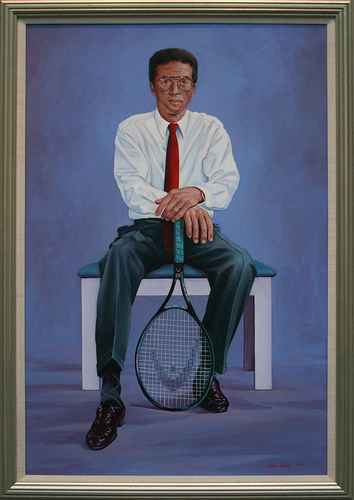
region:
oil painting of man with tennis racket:
[7, 9, 334, 479]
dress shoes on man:
[83, 367, 235, 453]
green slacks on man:
[100, 200, 254, 397]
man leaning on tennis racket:
[79, 36, 249, 450]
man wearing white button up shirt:
[80, 45, 245, 452]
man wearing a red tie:
[78, 44, 260, 452]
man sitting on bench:
[56, 48, 277, 446]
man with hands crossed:
[75, 31, 255, 452]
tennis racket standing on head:
[129, 202, 215, 417]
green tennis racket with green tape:
[130, 199, 217, 415]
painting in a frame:
[8, 10, 342, 480]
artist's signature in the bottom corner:
[265, 459, 308, 470]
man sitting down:
[75, 42, 275, 453]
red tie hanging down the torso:
[161, 127, 182, 213]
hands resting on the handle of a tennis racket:
[156, 185, 214, 252]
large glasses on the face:
[153, 72, 194, 93]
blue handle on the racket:
[168, 223, 189, 262]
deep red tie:
[162, 125, 185, 251]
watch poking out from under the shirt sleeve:
[197, 189, 210, 204]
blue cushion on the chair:
[76, 244, 278, 277]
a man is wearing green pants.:
[99, 294, 124, 338]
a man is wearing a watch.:
[192, 184, 204, 199]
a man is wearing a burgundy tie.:
[160, 119, 180, 189]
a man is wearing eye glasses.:
[150, 70, 193, 90]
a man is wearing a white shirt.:
[129, 138, 156, 175]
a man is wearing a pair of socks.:
[100, 369, 122, 395]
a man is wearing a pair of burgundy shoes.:
[84, 396, 125, 451]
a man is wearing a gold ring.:
[173, 200, 185, 212]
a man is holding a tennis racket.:
[129, 217, 218, 411]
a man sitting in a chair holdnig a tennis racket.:
[74, 46, 275, 452]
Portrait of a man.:
[0, 0, 351, 499]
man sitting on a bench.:
[84, 47, 252, 451]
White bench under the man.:
[72, 252, 284, 399]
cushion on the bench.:
[72, 258, 275, 278]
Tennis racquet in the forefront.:
[129, 207, 220, 415]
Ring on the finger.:
[170, 201, 185, 214]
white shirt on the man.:
[110, 45, 242, 232]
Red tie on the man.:
[109, 46, 240, 259]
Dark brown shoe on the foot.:
[79, 395, 132, 452]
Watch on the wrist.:
[188, 182, 210, 206]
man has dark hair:
[137, 43, 215, 92]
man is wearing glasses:
[159, 65, 203, 102]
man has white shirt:
[128, 108, 216, 212]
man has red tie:
[154, 124, 180, 210]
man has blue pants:
[113, 206, 253, 394]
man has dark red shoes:
[200, 360, 240, 420]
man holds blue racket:
[136, 238, 215, 414]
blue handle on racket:
[164, 214, 191, 274]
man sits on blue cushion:
[62, 231, 292, 320]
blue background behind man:
[243, 52, 296, 219]